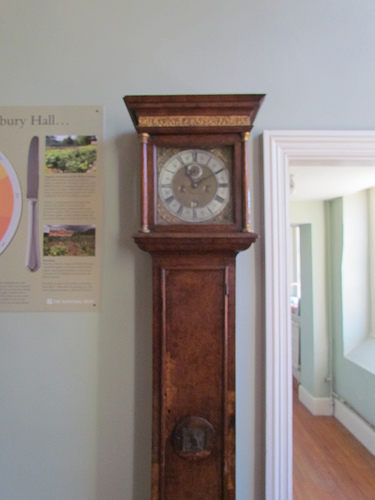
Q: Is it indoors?
A: Yes, it is indoors.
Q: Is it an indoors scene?
A: Yes, it is indoors.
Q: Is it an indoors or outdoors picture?
A: It is indoors.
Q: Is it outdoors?
A: No, it is indoors.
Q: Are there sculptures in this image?
A: No, there are no sculptures.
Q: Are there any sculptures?
A: No, there are no sculptures.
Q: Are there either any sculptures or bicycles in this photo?
A: No, there are no sculptures or bicycles.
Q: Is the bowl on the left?
A: Yes, the bowl is on the left of the image.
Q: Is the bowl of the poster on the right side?
A: No, the bowl is on the left of the image.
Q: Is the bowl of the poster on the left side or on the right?
A: The bowl is on the left of the image.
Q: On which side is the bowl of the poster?
A: The bowl is on the left of the image.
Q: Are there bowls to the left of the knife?
A: Yes, there is a bowl to the left of the knife.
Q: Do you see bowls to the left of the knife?
A: Yes, there is a bowl to the left of the knife.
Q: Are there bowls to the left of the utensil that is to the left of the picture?
A: Yes, there is a bowl to the left of the knife.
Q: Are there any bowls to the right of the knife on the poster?
A: No, the bowl is to the left of the knife.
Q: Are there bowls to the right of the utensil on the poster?
A: No, the bowl is to the left of the knife.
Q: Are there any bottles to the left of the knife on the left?
A: No, there is a bowl to the left of the knife.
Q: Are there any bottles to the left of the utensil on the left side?
A: No, there is a bowl to the left of the knife.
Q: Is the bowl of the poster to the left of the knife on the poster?
A: Yes, the bowl is to the left of the knife.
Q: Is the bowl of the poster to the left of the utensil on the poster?
A: Yes, the bowl is to the left of the knife.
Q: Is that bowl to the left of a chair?
A: No, the bowl is to the left of the knife.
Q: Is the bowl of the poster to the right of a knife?
A: No, the bowl is to the left of a knife.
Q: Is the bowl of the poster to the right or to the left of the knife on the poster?
A: The bowl is to the left of the knife.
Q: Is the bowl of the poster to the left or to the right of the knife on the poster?
A: The bowl is to the left of the knife.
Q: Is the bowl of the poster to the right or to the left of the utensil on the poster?
A: The bowl is to the left of the knife.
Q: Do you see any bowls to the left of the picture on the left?
A: Yes, there is a bowl to the left of the picture.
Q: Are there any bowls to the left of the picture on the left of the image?
A: Yes, there is a bowl to the left of the picture.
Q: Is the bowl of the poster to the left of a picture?
A: Yes, the bowl is to the left of a picture.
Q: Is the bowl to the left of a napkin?
A: No, the bowl is to the left of a picture.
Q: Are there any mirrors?
A: No, there are no mirrors.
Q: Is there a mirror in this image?
A: No, there are no mirrors.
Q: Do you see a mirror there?
A: No, there are no mirrors.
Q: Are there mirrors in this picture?
A: No, there are no mirrors.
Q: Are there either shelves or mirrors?
A: No, there are no mirrors or shelves.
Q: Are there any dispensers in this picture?
A: No, there are no dispensers.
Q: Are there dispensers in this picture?
A: No, there are no dispensers.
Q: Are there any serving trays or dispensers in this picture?
A: No, there are no dispensers or serving trays.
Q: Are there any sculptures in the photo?
A: No, there are no sculptures.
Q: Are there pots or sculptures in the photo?
A: No, there are no sculptures or pots.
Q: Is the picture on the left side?
A: Yes, the picture is on the left of the image.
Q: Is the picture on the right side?
A: No, the picture is on the left of the image.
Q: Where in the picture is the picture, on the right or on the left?
A: The picture is on the left of the image.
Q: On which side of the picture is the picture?
A: The picture is on the left of the image.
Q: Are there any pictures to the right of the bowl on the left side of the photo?
A: Yes, there is a picture to the right of the bowl.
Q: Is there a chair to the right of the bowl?
A: No, there is a picture to the right of the bowl.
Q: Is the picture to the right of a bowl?
A: Yes, the picture is to the right of a bowl.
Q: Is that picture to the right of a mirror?
A: No, the picture is to the right of a bowl.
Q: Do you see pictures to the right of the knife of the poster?
A: Yes, there is a picture to the right of the knife.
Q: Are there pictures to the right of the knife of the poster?
A: Yes, there is a picture to the right of the knife.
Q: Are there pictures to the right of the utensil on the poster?
A: Yes, there is a picture to the right of the knife.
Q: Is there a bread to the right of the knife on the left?
A: No, there is a picture to the right of the knife.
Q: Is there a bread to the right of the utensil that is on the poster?
A: No, there is a picture to the right of the knife.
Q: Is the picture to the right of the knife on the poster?
A: Yes, the picture is to the right of the knife.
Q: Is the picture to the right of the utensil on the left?
A: Yes, the picture is to the right of the knife.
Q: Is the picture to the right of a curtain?
A: No, the picture is to the right of the knife.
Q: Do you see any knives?
A: Yes, there is a knife.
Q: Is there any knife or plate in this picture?
A: Yes, there is a knife.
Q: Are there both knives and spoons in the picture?
A: No, there is a knife but no spoons.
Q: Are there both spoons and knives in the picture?
A: No, there is a knife but no spoons.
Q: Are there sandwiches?
A: No, there are no sandwiches.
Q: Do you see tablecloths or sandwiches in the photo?
A: No, there are no sandwiches or tablecloths.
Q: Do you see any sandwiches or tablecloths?
A: No, there are no sandwiches or tablecloths.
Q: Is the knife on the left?
A: Yes, the knife is on the left of the image.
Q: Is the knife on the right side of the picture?
A: No, the knife is on the left of the image.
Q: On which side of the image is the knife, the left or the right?
A: The knife is on the left of the image.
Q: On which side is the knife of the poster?
A: The knife is on the left of the image.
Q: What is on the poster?
A: The knife is on the poster.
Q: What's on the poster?
A: The knife is on the poster.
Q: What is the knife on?
A: The knife is on the poster.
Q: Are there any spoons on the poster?
A: No, there is a knife on the poster.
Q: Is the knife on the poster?
A: Yes, the knife is on the poster.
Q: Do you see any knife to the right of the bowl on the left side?
A: Yes, there is a knife to the right of the bowl.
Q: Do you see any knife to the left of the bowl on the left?
A: No, the knife is to the right of the bowl.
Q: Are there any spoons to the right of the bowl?
A: No, there is a knife to the right of the bowl.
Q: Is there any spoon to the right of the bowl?
A: No, there is a knife to the right of the bowl.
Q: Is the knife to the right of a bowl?
A: Yes, the knife is to the right of a bowl.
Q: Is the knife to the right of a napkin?
A: No, the knife is to the right of a bowl.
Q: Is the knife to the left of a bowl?
A: No, the knife is to the right of a bowl.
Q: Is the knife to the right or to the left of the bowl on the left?
A: The knife is to the right of the bowl.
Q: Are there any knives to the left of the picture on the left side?
A: Yes, there is a knife to the left of the picture.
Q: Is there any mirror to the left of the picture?
A: No, there is a knife to the left of the picture.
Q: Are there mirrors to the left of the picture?
A: No, there is a knife to the left of the picture.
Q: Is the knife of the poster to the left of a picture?
A: Yes, the knife is to the left of a picture.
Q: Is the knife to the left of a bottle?
A: No, the knife is to the left of a picture.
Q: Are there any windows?
A: Yes, there is a window.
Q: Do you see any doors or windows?
A: Yes, there is a window.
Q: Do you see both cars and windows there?
A: No, there is a window but no cars.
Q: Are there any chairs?
A: No, there are no chairs.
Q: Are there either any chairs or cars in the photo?
A: No, there are no chairs or cars.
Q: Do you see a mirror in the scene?
A: No, there are no mirrors.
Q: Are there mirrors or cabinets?
A: No, there are no mirrors or cabinets.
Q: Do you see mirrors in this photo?
A: No, there are no mirrors.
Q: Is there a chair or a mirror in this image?
A: No, there are no mirrors or chairs.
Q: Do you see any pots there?
A: No, there are no pots.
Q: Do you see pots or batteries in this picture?
A: No, there are no pots or batteries.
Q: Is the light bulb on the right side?
A: Yes, the light bulb is on the right of the image.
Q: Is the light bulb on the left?
A: No, the light bulb is on the right of the image.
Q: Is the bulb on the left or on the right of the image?
A: The bulb is on the right of the image.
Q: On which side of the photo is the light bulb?
A: The light bulb is on the right of the image.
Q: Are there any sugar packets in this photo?
A: No, there are no sugar packets.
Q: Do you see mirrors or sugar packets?
A: No, there are no sugar packets or mirrors.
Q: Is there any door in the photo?
A: Yes, there is a door.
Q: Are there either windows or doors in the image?
A: Yes, there is a door.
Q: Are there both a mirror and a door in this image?
A: No, there is a door but no mirrors.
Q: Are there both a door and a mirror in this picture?
A: No, there is a door but no mirrors.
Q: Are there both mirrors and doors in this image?
A: No, there is a door but no mirrors.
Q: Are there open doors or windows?
A: Yes, there is an open door.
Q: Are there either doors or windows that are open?
A: Yes, the door is open.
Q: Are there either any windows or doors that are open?
A: Yes, the door is open.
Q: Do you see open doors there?
A: Yes, there is an open door.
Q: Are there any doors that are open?
A: Yes, there is a door that is open.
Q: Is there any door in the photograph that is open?
A: Yes, there is a door that is open.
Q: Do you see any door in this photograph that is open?
A: Yes, there is a door that is open.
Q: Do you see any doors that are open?
A: Yes, there is a door that is open.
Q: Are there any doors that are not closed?
A: Yes, there is a open door.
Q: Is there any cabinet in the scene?
A: No, there are no cabinets.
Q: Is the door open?
A: Yes, the door is open.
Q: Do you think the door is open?
A: Yes, the door is open.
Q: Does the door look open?
A: Yes, the door is open.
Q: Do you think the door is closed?
A: No, the door is open.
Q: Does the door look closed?
A: No, the door is open.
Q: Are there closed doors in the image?
A: No, there is a door but it is open.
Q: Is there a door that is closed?
A: No, there is a door but it is open.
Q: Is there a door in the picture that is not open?
A: No, there is a door but it is open.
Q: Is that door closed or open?
A: The door is open.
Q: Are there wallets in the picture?
A: No, there are no wallets.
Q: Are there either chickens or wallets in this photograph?
A: No, there are no wallets or chickens.